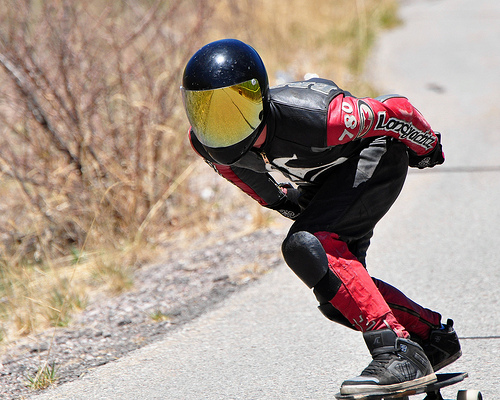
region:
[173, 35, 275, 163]
Black helmet covering face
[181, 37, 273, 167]
Helmet on persons head with yellow shade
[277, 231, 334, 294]
Black knee pads protecting knees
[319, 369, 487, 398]
Skateboard on asphalt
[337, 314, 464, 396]
Pair of black shoes on skateboard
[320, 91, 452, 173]
Left hand extended backwards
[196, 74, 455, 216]
Black and Red jacket with logo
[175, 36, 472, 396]
Skateboarder moving towards objective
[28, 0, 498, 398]
Asphalt surface for riding skateboards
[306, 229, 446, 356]
Red bottom leg pants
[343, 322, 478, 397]
black and white shoes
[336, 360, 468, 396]
black skateboard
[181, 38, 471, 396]
skateboarder in street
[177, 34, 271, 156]
black and yellow helmet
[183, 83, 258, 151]
yellow part of helmet that covers the face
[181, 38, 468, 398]
skateboarder in red and black suit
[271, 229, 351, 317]
black kneepads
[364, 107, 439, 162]
black letters on his left arm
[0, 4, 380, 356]
green and yellow dry grass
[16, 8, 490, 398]
gray pavement in the floor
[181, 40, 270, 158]
the skater is wearing a helmet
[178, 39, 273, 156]
the helmet is black in color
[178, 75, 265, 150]
the helmet has a visor on it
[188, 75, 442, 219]
the skater is wearing a jacket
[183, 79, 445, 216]
the jacket is black and red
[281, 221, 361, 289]
the skater is wearing knee pads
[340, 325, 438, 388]
the skater is wearing black shoes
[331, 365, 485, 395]
the skateboard is going downhill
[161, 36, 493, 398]
the skater is going downhill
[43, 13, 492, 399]
the road is grey in color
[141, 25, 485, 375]
the person on the skateboard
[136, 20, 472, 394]
the person going downhill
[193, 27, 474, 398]
the person on the road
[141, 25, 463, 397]
the person skateboarding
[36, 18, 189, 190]
the tall dry grass beside the road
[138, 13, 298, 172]
the helmet on the head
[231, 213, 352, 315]
the knee pad on the knee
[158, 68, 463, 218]
the person wearing a leather jacket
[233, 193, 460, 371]
the person wearing red pants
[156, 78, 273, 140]
the visor is reflective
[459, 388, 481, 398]
a white skateboard wheel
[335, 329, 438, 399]
a boy's black tennis shoe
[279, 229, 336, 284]
a black knee pad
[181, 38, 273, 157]
a black and yellow skateboard helmet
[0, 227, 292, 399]
dirt and rocks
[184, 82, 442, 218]
a man's black and red jacket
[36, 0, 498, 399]
a concrete walkway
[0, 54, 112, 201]
a gray tree branch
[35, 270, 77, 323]
a small section of green grass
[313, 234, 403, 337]
part of a red pant's leg